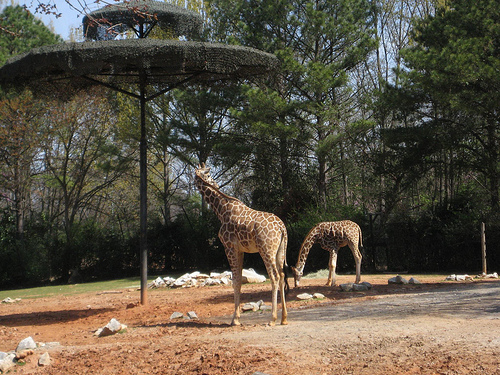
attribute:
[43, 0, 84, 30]
sky — blue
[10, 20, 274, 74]
structure — elevated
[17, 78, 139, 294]
trees — green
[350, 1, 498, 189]
tree leaves — green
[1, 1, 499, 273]
trees — green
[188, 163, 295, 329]
giraffe — adult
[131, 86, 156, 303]
pole — black , metal 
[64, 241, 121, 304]
grass — green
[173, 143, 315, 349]
giraffe — looking, standing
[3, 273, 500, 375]
ground — flat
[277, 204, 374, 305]
giraffe — young, eating, standing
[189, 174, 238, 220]
neck — curved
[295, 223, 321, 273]
neck — curved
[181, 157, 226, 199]
head — turned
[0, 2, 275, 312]
umbrella — tall, metal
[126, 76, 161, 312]
pole — black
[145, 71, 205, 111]
support — black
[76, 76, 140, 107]
support — black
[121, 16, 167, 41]
support — black